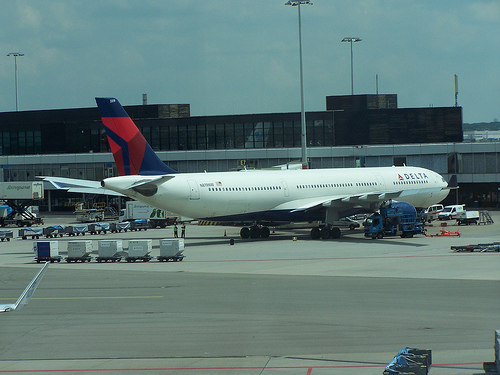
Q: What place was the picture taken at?
A: It was taken at the airport.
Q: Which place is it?
A: It is an airport.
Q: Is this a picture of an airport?
A: Yes, it is showing an airport.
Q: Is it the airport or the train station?
A: It is the airport.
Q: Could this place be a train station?
A: No, it is an airport.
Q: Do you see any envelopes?
A: No, there are no envelopes.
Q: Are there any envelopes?
A: No, there are no envelopes.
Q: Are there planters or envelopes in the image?
A: No, there are no envelopes or planters.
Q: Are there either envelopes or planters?
A: No, there are no envelopes or planters.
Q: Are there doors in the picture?
A: Yes, there is a door.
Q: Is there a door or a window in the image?
A: Yes, there is a door.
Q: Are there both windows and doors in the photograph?
A: Yes, there are both a door and a window.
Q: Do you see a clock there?
A: No, there are no clocks.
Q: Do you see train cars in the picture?
A: No, there are no train cars.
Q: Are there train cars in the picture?
A: No, there are no train cars.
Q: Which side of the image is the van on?
A: The van is on the right of the image.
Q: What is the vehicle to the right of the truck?
A: The vehicle is a van.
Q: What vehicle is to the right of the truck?
A: The vehicle is a van.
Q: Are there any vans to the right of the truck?
A: Yes, there is a van to the right of the truck.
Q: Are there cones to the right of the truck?
A: No, there is a van to the right of the truck.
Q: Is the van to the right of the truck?
A: Yes, the van is to the right of the truck.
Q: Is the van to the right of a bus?
A: No, the van is to the right of the truck.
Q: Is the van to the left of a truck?
A: No, the van is to the right of a truck.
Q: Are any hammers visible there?
A: No, there are no hammers.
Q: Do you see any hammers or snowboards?
A: No, there are no hammers or snowboards.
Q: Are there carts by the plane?
A: Yes, there is a cart by the plane.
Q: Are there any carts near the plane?
A: Yes, there is a cart near the plane.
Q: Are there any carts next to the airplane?
A: Yes, there is a cart next to the airplane.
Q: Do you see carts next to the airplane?
A: Yes, there is a cart next to the airplane.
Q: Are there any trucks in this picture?
A: Yes, there is a truck.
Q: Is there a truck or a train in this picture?
A: Yes, there is a truck.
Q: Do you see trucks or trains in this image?
A: Yes, there is a truck.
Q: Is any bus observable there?
A: No, there are no buses.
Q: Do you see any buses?
A: No, there are no buses.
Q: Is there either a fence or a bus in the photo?
A: No, there are no buses or fences.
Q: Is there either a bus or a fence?
A: No, there are no buses or fences.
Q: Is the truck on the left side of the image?
A: No, the truck is on the right of the image.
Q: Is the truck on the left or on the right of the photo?
A: The truck is on the right of the image.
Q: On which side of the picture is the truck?
A: The truck is on the right of the image.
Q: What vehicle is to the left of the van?
A: The vehicle is a truck.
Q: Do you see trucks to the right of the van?
A: No, the truck is to the left of the van.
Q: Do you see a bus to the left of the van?
A: No, there is a truck to the left of the van.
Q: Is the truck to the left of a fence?
A: No, the truck is to the left of the van.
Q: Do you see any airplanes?
A: Yes, there is an airplane.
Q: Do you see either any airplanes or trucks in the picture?
A: Yes, there is an airplane.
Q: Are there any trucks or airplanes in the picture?
A: Yes, there is an airplane.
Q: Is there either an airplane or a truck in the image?
A: Yes, there is an airplane.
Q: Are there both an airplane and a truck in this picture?
A: Yes, there are both an airplane and a truck.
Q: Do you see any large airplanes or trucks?
A: Yes, there is a large airplane.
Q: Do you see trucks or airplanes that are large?
A: Yes, the airplane is large.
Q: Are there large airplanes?
A: Yes, there is a large airplane.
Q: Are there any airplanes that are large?
A: Yes, there is an airplane that is large.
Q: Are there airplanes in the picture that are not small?
A: Yes, there is a large airplane.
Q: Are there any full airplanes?
A: Yes, there is a full airplane.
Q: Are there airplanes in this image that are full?
A: Yes, there is an airplane that is full.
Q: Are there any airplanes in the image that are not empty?
A: Yes, there is an full airplane.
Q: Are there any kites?
A: No, there are no kites.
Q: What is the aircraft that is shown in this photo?
A: The aircraft is an airplane.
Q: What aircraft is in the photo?
A: The aircraft is an airplane.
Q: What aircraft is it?
A: The aircraft is an airplane.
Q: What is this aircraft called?
A: This is an airplane.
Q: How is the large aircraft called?
A: The aircraft is an airplane.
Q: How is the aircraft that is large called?
A: The aircraft is an airplane.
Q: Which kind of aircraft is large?
A: The aircraft is an airplane.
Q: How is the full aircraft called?
A: The aircraft is an airplane.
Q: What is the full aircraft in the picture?
A: The aircraft is an airplane.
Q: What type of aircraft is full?
A: The aircraft is an airplane.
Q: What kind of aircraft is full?
A: The aircraft is an airplane.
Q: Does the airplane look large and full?
A: Yes, the airplane is large and full.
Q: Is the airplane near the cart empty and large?
A: No, the airplane is large but full.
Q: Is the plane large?
A: Yes, the plane is large.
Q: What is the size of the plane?
A: The plane is large.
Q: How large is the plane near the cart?
A: The airplane is large.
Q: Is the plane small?
A: No, the plane is large.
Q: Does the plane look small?
A: No, the plane is large.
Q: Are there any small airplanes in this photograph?
A: No, there is an airplane but it is large.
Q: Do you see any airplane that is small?
A: No, there is an airplane but it is large.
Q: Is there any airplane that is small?
A: No, there is an airplane but it is large.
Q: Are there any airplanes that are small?
A: No, there is an airplane but it is large.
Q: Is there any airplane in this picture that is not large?
A: No, there is an airplane but it is large.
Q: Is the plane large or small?
A: The plane is large.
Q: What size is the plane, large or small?
A: The plane is large.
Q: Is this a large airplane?
A: Yes, this is a large airplane.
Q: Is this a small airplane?
A: No, this is a large airplane.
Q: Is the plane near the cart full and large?
A: Yes, the airplane is full and large.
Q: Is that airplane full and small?
A: No, the airplane is full but large.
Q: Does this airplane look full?
A: Yes, the airplane is full.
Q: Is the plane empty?
A: No, the plane is full.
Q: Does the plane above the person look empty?
A: No, the plane is full.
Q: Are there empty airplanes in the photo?
A: No, there is an airplane but it is full.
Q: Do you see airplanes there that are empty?
A: No, there is an airplane but it is full.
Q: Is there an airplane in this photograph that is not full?
A: No, there is an airplane but it is full.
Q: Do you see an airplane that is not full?
A: No, there is an airplane but it is full.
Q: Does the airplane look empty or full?
A: The airplane is full.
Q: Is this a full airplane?
A: Yes, this is a full airplane.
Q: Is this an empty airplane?
A: No, this is a full airplane.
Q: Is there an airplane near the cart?
A: Yes, there is an airplane near the cart.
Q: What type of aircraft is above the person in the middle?
A: The aircraft is an airplane.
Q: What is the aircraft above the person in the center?
A: The aircraft is an airplane.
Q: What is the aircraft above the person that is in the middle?
A: The aircraft is an airplane.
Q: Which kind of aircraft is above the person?
A: The aircraft is an airplane.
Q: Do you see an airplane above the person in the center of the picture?
A: Yes, there is an airplane above the person.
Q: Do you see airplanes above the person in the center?
A: Yes, there is an airplane above the person.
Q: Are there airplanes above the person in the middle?
A: Yes, there is an airplane above the person.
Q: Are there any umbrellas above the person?
A: No, there is an airplane above the person.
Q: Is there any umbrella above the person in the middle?
A: No, there is an airplane above the person.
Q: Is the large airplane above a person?
A: Yes, the plane is above a person.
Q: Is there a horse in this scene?
A: No, there are no horses.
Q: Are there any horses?
A: No, there are no horses.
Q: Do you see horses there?
A: No, there are no horses.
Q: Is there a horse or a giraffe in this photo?
A: No, there are no horses or giraffes.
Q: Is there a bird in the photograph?
A: No, there are no birds.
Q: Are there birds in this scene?
A: No, there are no birds.